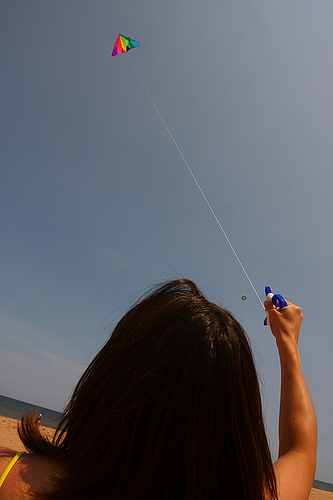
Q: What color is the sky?
A: Blue.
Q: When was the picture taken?
A: Daytime.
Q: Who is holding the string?
A: The woman.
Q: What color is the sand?
A: Brown.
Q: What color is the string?
A: White.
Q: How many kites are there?
A: One.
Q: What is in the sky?
A: A kite.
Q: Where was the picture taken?
A: Beach.